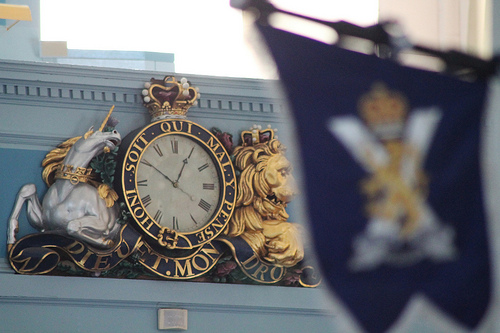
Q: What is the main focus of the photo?
A: Clock.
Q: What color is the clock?
A: Gold and silver.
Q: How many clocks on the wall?
A: One.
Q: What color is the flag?
A: Blue, white and gold.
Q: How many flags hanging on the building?
A: One.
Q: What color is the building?
A: Blue.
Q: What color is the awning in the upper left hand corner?
A: Yellow.